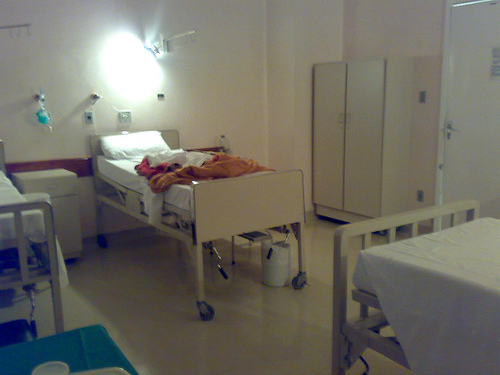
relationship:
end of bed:
[189, 179, 347, 186] [76, 110, 317, 231]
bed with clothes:
[76, 110, 317, 231] [128, 145, 248, 186]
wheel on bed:
[193, 294, 229, 324] [76, 110, 317, 231]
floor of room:
[94, 273, 256, 368] [4, 9, 499, 311]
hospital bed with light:
[76, 110, 317, 231] [93, 34, 178, 110]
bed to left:
[76, 110, 317, 231] [28, 133, 72, 212]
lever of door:
[439, 120, 471, 151] [414, 15, 498, 180]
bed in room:
[76, 110, 317, 231] [4, 9, 499, 311]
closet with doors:
[311, 59, 395, 232] [331, 68, 361, 205]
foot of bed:
[190, 221, 332, 245] [76, 110, 317, 231]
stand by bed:
[82, 91, 115, 115] [76, 110, 317, 231]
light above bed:
[93, 34, 178, 110] [76, 110, 317, 231]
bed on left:
[76, 110, 317, 231] [28, 133, 72, 212]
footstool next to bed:
[232, 229, 273, 259] [247, 176, 292, 271]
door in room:
[414, 15, 498, 180] [4, 9, 499, 354]